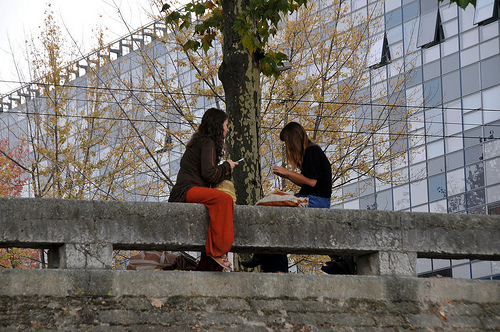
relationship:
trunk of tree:
[215, 36, 265, 168] [207, 13, 258, 109]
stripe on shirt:
[208, 147, 221, 171] [171, 130, 225, 198]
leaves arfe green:
[197, 10, 276, 49] [193, 30, 219, 43]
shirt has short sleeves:
[306, 146, 338, 207] [306, 150, 320, 181]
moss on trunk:
[248, 76, 260, 159] [215, 36, 265, 168]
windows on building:
[41, 98, 163, 195] [25, 1, 498, 160]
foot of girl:
[218, 258, 241, 274] [169, 105, 240, 274]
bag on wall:
[258, 189, 304, 214] [96, 203, 419, 271]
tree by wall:
[207, 13, 258, 109] [96, 203, 419, 271]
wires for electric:
[22, 82, 158, 139] [448, 110, 493, 142]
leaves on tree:
[197, 10, 276, 49] [207, 13, 258, 109]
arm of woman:
[270, 163, 329, 193] [273, 125, 333, 210]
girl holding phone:
[169, 105, 240, 274] [228, 147, 256, 187]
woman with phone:
[273, 125, 333, 210] [272, 157, 288, 176]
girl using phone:
[208, 115, 228, 239] [228, 147, 256, 187]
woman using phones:
[239, 120, 334, 270] [234, 148, 290, 176]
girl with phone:
[169, 105, 240, 274] [228, 147, 256, 187]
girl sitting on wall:
[169, 105, 240, 274] [96, 203, 419, 271]